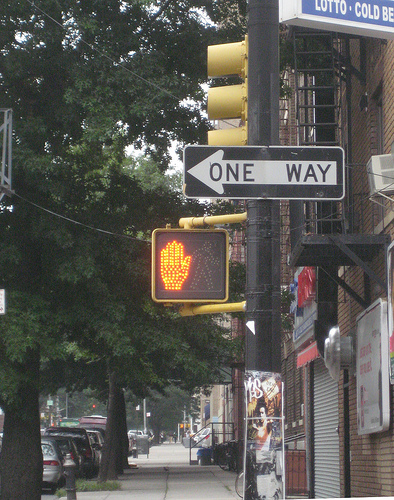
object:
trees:
[1, 0, 239, 499]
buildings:
[190, 3, 394, 496]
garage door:
[301, 328, 344, 499]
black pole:
[241, 0, 283, 499]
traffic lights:
[148, 224, 228, 303]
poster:
[244, 370, 286, 498]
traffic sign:
[182, 146, 345, 198]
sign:
[354, 296, 390, 436]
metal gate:
[313, 353, 342, 499]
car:
[44, 426, 92, 495]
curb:
[42, 438, 157, 500]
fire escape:
[289, 34, 393, 308]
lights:
[204, 30, 250, 149]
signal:
[149, 223, 231, 305]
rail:
[188, 418, 235, 464]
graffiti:
[241, 369, 289, 499]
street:
[8, 418, 293, 500]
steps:
[186, 411, 234, 466]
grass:
[79, 478, 91, 493]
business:
[187, 2, 393, 497]